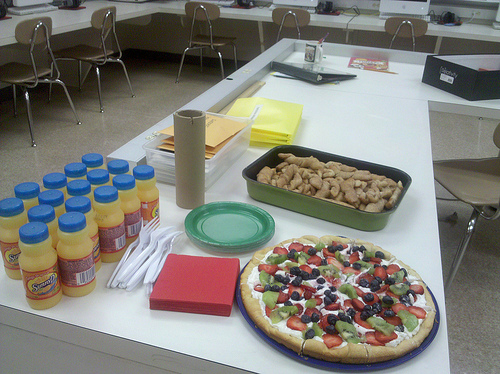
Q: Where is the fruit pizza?
A: On the table.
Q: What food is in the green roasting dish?
A: Chicken tenders.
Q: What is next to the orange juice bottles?
A: Forks.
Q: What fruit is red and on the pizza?
A: Strawberries.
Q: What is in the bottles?
A: Juice.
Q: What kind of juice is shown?
A: Orange Juice.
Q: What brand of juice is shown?
A: Sunny D.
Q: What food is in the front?
A: Pizza.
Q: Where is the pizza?
A: ON the tray.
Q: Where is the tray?
A: On the table.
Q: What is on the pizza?
A: Fruit.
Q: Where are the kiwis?
A: On the pizza.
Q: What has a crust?
A: Pizza pie.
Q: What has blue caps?
A: On bottles.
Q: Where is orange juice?
A: In bottles.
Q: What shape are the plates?
A: Round.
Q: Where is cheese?
A: On the pizza.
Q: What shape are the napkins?
A: Square.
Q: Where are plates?
A: On the table.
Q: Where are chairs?
A: Next to the tables.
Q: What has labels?
A: Orange juice bottles.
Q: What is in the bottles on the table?
A: Orange juice.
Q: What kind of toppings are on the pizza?
A: Fruit.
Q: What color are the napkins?
A: Red.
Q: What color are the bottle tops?
A: Blue.